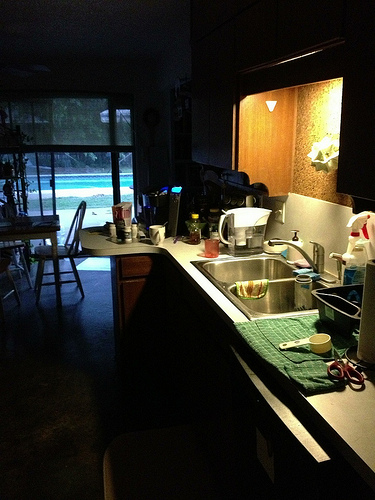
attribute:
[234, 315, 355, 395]
dish towel — green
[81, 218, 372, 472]
counter — cluttered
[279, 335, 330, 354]
measuring cup — white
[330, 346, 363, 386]
scissors — colorful, red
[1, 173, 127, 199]
pool — in-ground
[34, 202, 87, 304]
chair — wooden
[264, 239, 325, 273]
faucet — silver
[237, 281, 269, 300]
rag — brown, white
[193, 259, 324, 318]
sink — stainless steel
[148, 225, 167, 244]
cup — white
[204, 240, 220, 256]
cup — pink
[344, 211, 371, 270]
spray bottle — red, white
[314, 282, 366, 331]
dish drainer — black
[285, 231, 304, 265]
soap dispenser — white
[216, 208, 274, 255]
pitcher — white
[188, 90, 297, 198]
cabinet — brown